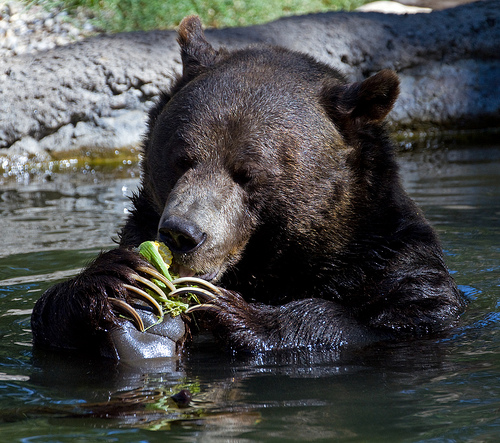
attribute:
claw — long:
[103, 296, 144, 333]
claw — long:
[119, 282, 163, 317]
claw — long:
[125, 274, 168, 308]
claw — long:
[133, 264, 175, 294]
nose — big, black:
[150, 210, 217, 263]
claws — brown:
[117, 263, 222, 333]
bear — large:
[43, 67, 402, 342]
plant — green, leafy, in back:
[119, 2, 181, 35]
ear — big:
[322, 51, 410, 134]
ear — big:
[174, 13, 229, 95]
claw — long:
[138, 263, 179, 290]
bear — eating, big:
[28, 15, 468, 372]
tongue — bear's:
[175, 265, 196, 279]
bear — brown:
[89, 13, 449, 399]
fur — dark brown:
[28, 10, 470, 403]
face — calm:
[160, 117, 293, 278]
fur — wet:
[161, 67, 451, 369]